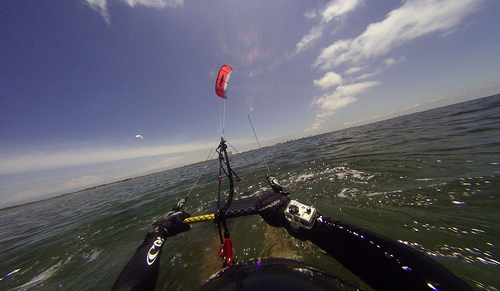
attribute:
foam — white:
[297, 158, 374, 201]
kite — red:
[121, 126, 146, 152]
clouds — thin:
[290, 2, 489, 138]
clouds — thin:
[72, 0, 201, 30]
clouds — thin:
[1, 121, 287, 215]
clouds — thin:
[332, 89, 499, 136]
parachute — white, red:
[111, 60, 466, 287]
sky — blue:
[0, 2, 495, 210]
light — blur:
[213, 18, 282, 118]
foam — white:
[231, 153, 395, 207]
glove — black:
[256, 190, 290, 225]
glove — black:
[152, 210, 194, 235]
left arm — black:
[112, 206, 195, 287]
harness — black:
[132, 117, 340, 253]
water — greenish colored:
[363, 88, 460, 239]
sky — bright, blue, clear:
[8, 0, 498, 170]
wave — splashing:
[289, 167, 379, 186]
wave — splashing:
[26, 249, 131, 263]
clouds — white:
[263, 7, 450, 117]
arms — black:
[143, 204, 378, 258]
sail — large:
[212, 61, 237, 103]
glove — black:
[156, 217, 188, 232]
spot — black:
[219, 73, 224, 90]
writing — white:
[159, 202, 309, 223]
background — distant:
[1, 180, 169, 219]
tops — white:
[278, 170, 396, 190]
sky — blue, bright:
[4, 4, 498, 184]